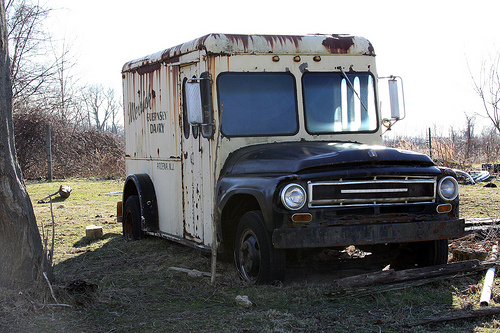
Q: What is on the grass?
A: An old truck.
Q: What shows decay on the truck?
A: Rust.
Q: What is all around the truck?
A: Debris.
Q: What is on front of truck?
A: Grill and lights.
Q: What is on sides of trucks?
A: Side view mirrors.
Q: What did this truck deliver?
A: Dairy products.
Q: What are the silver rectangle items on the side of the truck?
A: Rear view mirrors.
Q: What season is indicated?
A: Autumn.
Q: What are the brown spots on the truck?
A: Rust.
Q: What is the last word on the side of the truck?
A: Dairy.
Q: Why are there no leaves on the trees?
A: Autumn.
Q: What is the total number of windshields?
A: 2.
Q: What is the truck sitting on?
A: Grass.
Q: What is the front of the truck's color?
A: Black.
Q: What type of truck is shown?
A: Dairy.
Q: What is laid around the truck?
A: Wood.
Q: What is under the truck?
A: Grass.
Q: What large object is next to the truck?
A: Tree.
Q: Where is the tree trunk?
A: Left side.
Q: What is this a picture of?
A: A run-down vechile.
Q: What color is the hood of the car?
A: Black.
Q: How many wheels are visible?
A: Threee.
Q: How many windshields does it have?
A: Two.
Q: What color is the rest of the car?
A: White.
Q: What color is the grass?
A: Green.